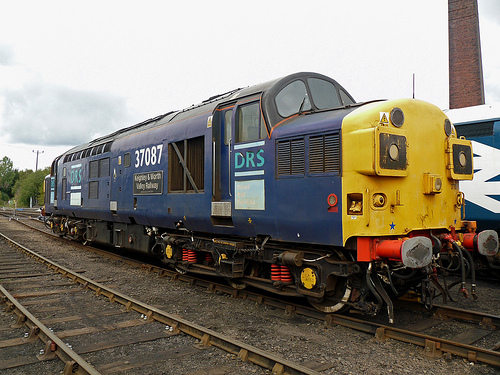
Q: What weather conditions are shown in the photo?
A: It is cloudy.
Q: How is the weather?
A: It is cloudy.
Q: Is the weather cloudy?
A: Yes, it is cloudy.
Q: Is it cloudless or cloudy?
A: It is cloudy.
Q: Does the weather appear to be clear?
A: No, it is cloudy.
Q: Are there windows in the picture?
A: Yes, there are windows.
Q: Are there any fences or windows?
A: Yes, there are windows.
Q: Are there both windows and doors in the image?
A: Yes, there are both windows and a door.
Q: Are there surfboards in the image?
A: No, there are no surfboards.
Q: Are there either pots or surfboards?
A: No, there are no surfboards or pots.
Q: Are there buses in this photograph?
A: No, there are no buses.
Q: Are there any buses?
A: No, there are no buses.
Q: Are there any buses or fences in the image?
A: No, there are no buses or fences.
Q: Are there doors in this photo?
A: Yes, there is a door.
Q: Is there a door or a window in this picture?
A: Yes, there is a door.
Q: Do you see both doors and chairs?
A: No, there is a door but no chairs.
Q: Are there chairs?
A: No, there are no chairs.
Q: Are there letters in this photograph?
A: Yes, there are letters.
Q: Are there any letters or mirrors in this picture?
A: Yes, there are letters.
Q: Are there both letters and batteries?
A: No, there are letters but no batteries.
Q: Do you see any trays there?
A: No, there are no trays.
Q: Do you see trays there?
A: No, there are no trays.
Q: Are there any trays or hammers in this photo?
A: No, there are no trays or hammers.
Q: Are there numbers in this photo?
A: Yes, there are numbers.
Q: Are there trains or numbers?
A: Yes, there are numbers.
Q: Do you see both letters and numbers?
A: Yes, there are both numbers and letters.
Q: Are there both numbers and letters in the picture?
A: Yes, there are both numbers and letters.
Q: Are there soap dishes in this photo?
A: No, there are no soap dishes.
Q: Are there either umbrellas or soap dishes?
A: No, there are no soap dishes or umbrellas.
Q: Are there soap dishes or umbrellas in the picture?
A: No, there are no soap dishes or umbrellas.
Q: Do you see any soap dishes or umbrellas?
A: No, there are no soap dishes or umbrellas.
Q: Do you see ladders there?
A: No, there are no ladders.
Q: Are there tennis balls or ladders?
A: No, there are no ladders or tennis balls.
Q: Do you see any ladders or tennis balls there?
A: No, there are no ladders or tennis balls.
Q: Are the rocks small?
A: Yes, the rocks are small.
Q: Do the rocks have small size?
A: Yes, the rocks are small.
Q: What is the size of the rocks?
A: The rocks are small.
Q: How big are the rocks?
A: The rocks are small.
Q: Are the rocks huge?
A: No, the rocks are small.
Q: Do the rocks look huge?
A: No, the rocks are small.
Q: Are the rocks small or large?
A: The rocks are small.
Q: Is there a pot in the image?
A: No, there are no pots.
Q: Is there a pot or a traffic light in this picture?
A: No, there are no pots or traffic lights.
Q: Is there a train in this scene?
A: Yes, there is a train.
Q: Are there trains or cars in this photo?
A: Yes, there is a train.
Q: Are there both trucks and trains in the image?
A: No, there is a train but no trucks.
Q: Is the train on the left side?
A: No, the train is on the right of the image.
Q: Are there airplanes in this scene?
A: No, there are no airplanes.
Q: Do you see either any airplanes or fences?
A: No, there are no airplanes or fences.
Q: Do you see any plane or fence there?
A: No, there are no airplanes or fences.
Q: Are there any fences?
A: No, there are no fences.